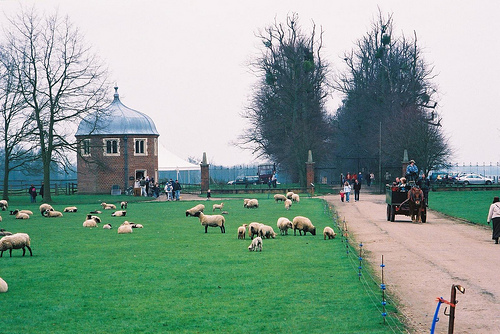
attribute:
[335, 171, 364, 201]
family — one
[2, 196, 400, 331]
grass — green 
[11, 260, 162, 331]
green grass — green 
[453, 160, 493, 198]
car — silver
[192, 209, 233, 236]
sheep — white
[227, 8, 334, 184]
tree — tall, bare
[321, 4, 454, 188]
tree — tall, bare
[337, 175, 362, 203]
family — small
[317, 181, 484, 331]
road — dirt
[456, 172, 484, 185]
car — silver